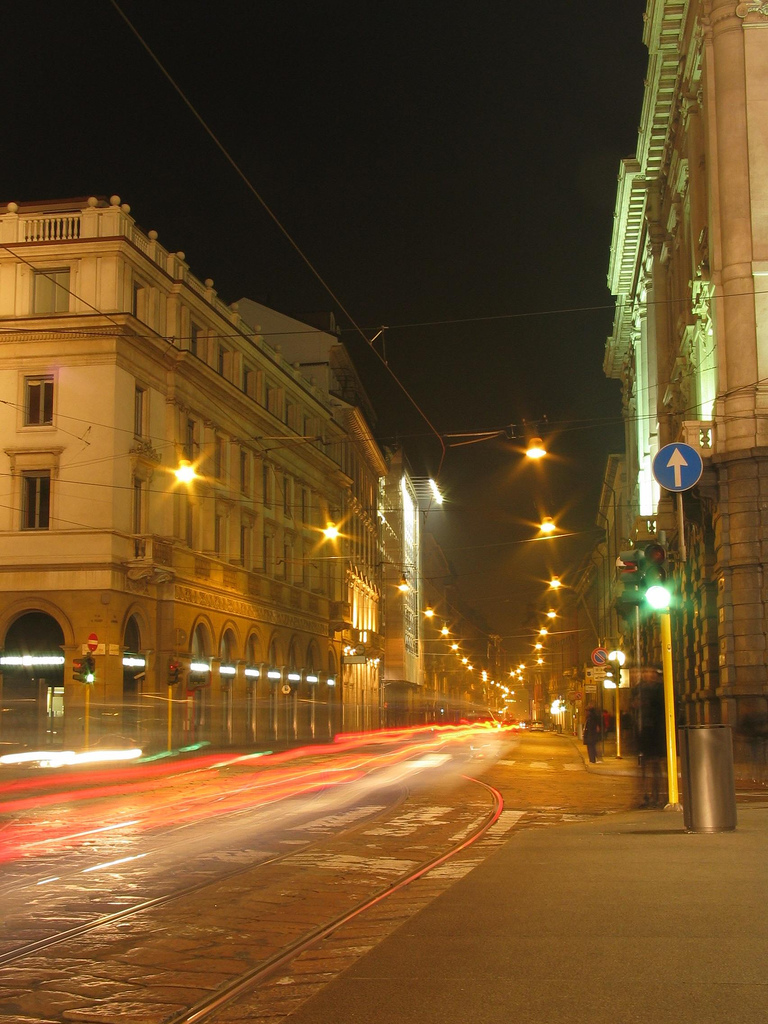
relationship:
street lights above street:
[401, 416, 569, 721] [3, 718, 570, 1021]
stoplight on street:
[72, 649, 96, 751] [0, 720, 525, 1011]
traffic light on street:
[620, 525, 689, 805] [0, 720, 525, 1011]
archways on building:
[2, 603, 348, 741] [3, 191, 356, 791]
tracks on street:
[0, 759, 508, 1022] [3, 718, 570, 1021]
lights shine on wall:
[425, 475, 443, 507] [392, 464, 423, 687]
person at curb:
[582, 704, 599, 762] [562, 730, 596, 767]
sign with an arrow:
[649, 440, 703, 492] [665, 446, 684, 488]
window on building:
[19, 468, 50, 527] [2, 194, 381, 737]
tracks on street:
[5, 719, 560, 1020] [0, 720, 768, 1021]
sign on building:
[163, 582, 331, 637] [2, 194, 381, 737]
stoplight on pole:
[72, 643, 95, 753] [56, 627, 123, 765]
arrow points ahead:
[654, 436, 701, 491] [197, 587, 752, 944]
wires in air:
[110, 4, 588, 501] [4, 67, 758, 835]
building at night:
[2, 194, 381, 737] [3, 72, 677, 507]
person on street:
[582, 704, 599, 761] [3, 718, 570, 1021]